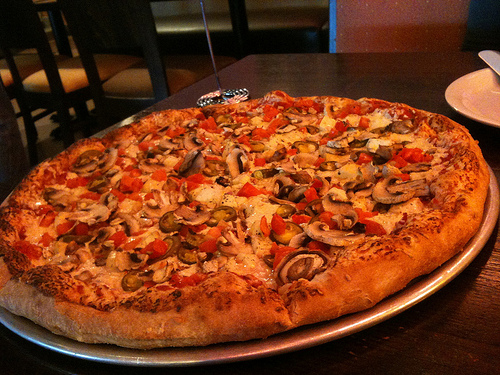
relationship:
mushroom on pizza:
[273, 249, 332, 287] [5, 74, 488, 362]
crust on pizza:
[0, 269, 291, 350] [28, 90, 490, 370]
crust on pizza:
[2, 260, 292, 350] [5, 74, 488, 362]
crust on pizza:
[0, 269, 291, 350] [58, 118, 471, 344]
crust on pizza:
[0, 269, 291, 350] [5, 74, 488, 362]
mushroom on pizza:
[273, 249, 332, 287] [0, 90, 495, 354]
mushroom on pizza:
[277, 245, 331, 287] [5, 74, 488, 362]